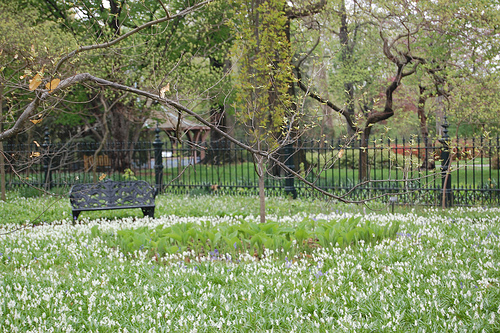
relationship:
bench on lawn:
[66, 178, 156, 216] [11, 221, 492, 330]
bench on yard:
[66, 178, 156, 216] [11, 221, 492, 330]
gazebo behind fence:
[141, 105, 209, 167] [9, 132, 483, 204]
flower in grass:
[0, 221, 181, 239] [11, 221, 492, 330]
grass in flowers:
[11, 221, 492, 330] [0, 221, 181, 239]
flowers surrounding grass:
[0, 221, 181, 239] [11, 221, 492, 330]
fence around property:
[9, 132, 483, 204] [3, 136, 500, 332]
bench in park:
[66, 178, 156, 216] [11, 221, 492, 330]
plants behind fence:
[391, 140, 480, 160] [9, 132, 483, 204]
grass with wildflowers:
[11, 221, 492, 330] [2, 215, 175, 248]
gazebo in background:
[141, 105, 209, 167] [1, 2, 500, 174]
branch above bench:
[0, 71, 355, 207] [66, 178, 156, 216]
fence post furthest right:
[9, 132, 483, 204] [242, 1, 499, 332]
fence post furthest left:
[9, 132, 483, 204] [1, 1, 262, 332]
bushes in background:
[391, 140, 480, 160] [1, 2, 500, 174]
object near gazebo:
[160, 82, 172, 99] [141, 105, 209, 167]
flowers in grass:
[0, 221, 181, 239] [11, 221, 492, 330]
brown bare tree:
[362, 112, 376, 181] [287, 2, 427, 188]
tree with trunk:
[287, 2, 427, 188] [354, 129, 373, 185]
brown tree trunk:
[362, 112, 376, 181] [354, 129, 373, 185]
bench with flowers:
[66, 178, 156, 216] [2, 215, 175, 248]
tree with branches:
[287, 2, 427, 188] [288, 0, 426, 143]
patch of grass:
[118, 215, 400, 252] [11, 221, 492, 330]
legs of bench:
[72, 206, 155, 222] [66, 178, 156, 216]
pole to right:
[440, 92, 455, 210] [242, 1, 499, 332]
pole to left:
[41, 129, 56, 189] [1, 1, 262, 332]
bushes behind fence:
[391, 140, 480, 160] [9, 132, 483, 204]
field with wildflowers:
[11, 221, 492, 330] [2, 215, 175, 248]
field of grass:
[1, 148, 500, 196] [7, 166, 499, 207]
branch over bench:
[0, 71, 355, 207] [66, 178, 156, 216]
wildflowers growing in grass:
[2, 215, 175, 248] [7, 166, 499, 207]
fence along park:
[9, 132, 483, 204] [3, 179, 500, 332]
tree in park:
[287, 2, 427, 188] [3, 179, 500, 332]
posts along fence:
[38, 126, 452, 208] [9, 132, 483, 204]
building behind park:
[141, 105, 209, 167] [3, 179, 500, 332]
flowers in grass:
[207, 243, 223, 260] [7, 166, 499, 207]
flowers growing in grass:
[300, 235, 319, 263] [7, 166, 499, 207]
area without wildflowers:
[118, 215, 400, 252] [2, 215, 175, 248]